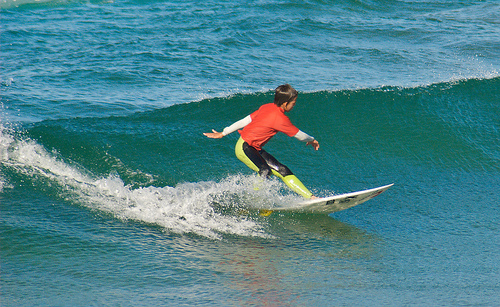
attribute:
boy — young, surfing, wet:
[203, 84, 320, 202]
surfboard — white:
[255, 182, 397, 210]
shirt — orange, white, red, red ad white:
[235, 102, 299, 151]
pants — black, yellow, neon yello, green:
[235, 135, 310, 206]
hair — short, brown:
[273, 84, 298, 108]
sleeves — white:
[218, 115, 314, 144]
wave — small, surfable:
[1, 73, 498, 236]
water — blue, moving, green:
[5, 3, 491, 306]